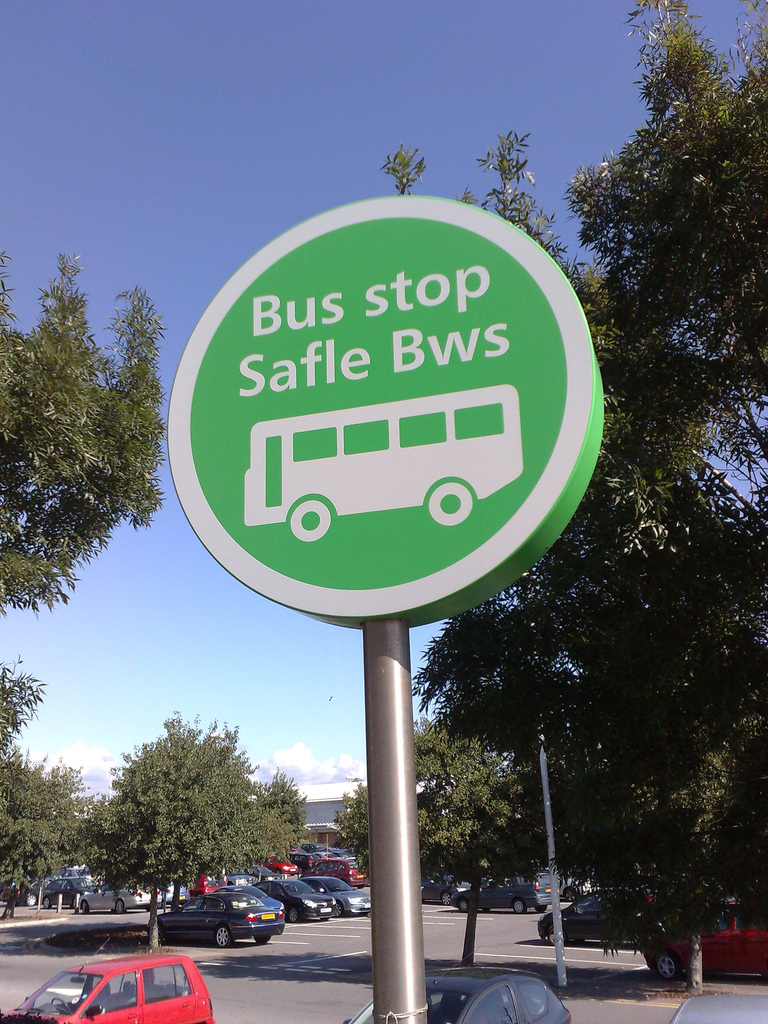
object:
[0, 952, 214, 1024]
vehicle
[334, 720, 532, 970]
tree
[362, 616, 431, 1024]
metal pole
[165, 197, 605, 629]
sign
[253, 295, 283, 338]
letter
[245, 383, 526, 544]
bus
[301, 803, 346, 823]
wall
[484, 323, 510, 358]
white letters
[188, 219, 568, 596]
green background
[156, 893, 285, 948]
car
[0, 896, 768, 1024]
lot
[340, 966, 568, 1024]
car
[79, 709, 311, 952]
tree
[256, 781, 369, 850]
building